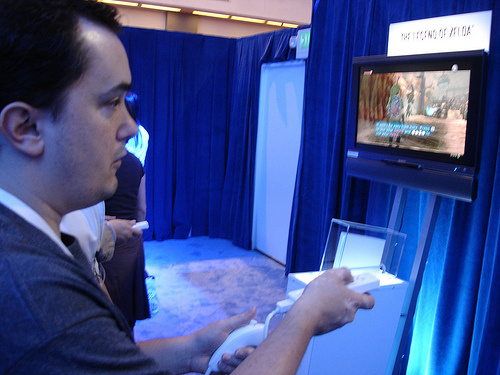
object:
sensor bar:
[333, 141, 487, 184]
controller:
[267, 262, 387, 325]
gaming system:
[262, 212, 417, 373]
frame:
[235, 51, 315, 273]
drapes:
[442, 224, 487, 293]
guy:
[0, 0, 382, 373]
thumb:
[315, 260, 362, 290]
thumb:
[222, 298, 265, 330]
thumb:
[115, 215, 142, 227]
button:
[334, 262, 387, 297]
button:
[241, 313, 262, 331]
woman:
[84, 90, 166, 352]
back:
[98, 144, 153, 224]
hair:
[107, 87, 147, 156]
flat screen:
[327, 38, 499, 206]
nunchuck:
[184, 311, 273, 375]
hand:
[278, 260, 386, 345]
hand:
[182, 295, 269, 373]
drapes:
[77, 23, 204, 252]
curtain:
[172, 28, 283, 256]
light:
[280, 20, 304, 32]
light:
[263, 16, 284, 31]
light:
[230, 12, 268, 30]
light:
[190, 5, 232, 25]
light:
[137, 0, 185, 18]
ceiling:
[85, 0, 322, 43]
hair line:
[51, 8, 112, 84]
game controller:
[190, 308, 281, 374]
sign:
[374, 5, 496, 62]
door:
[235, 50, 312, 268]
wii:
[265, 209, 421, 375]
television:
[320, 38, 496, 213]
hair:
[0, 1, 129, 135]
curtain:
[280, 0, 498, 374]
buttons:
[370, 152, 482, 181]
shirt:
[0, 179, 188, 375]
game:
[179, 207, 434, 374]